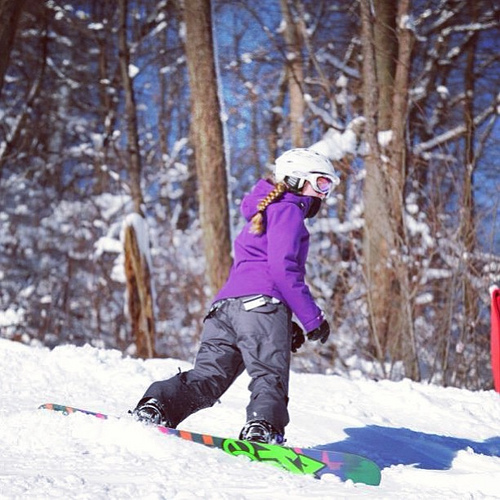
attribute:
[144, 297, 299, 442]
pants — gray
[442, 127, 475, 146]
wall — braided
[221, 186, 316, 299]
jacket — purple, hooded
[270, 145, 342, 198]
helmet — white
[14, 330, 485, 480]
snow — covered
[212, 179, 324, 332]
jacket — purple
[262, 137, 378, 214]
helmet — white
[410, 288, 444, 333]
light — green, neon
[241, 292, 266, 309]
card — small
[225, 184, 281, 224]
light — neon, green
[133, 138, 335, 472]
person — snowboarding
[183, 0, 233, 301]
trunk — brown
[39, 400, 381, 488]
snowboard — used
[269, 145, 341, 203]
helmet — white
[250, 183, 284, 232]
hair — blonde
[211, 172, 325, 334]
sweater — purple